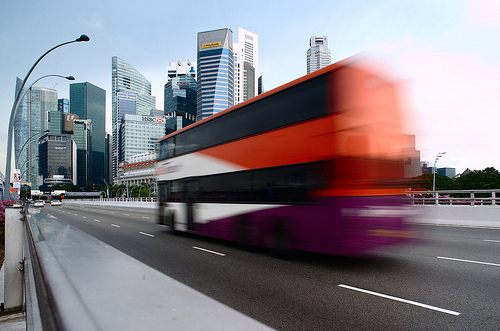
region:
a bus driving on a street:
[141, 125, 443, 272]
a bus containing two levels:
[146, 129, 383, 256]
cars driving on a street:
[33, 193, 69, 208]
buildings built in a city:
[66, 84, 199, 132]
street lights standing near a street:
[0, 39, 78, 204]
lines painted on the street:
[79, 209, 161, 259]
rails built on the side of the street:
[435, 183, 499, 219]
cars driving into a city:
[26, 184, 69, 215]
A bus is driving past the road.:
[143, 52, 431, 259]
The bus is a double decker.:
[148, 53, 412, 257]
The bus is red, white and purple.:
[151, 57, 413, 260]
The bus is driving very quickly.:
[148, 50, 435, 262]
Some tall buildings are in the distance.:
[15, 28, 342, 196]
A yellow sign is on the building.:
[196, 30, 232, 52]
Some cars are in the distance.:
[26, 187, 69, 210]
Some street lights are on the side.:
[1, 27, 98, 208]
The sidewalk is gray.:
[26, 200, 281, 329]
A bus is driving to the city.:
[0, 0, 497, 330]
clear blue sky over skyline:
[1, 0, 493, 175]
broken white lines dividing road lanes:
[30, 200, 490, 326]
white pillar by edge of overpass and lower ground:
[0, 195, 35, 325]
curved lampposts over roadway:
[5, 30, 91, 210]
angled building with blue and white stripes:
[195, 25, 232, 115]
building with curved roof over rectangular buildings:
[110, 52, 160, 192]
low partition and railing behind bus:
[345, 181, 495, 226]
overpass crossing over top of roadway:
[21, 180, 106, 210]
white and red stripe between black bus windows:
[151, 62, 359, 202]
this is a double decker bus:
[135, 65, 413, 292]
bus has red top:
[116, 67, 411, 177]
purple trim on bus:
[145, 181, 450, 291]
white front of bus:
[126, 138, 271, 241]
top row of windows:
[133, 74, 350, 152]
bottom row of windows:
[154, 167, 336, 219]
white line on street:
[336, 267, 460, 327]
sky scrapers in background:
[0, 18, 314, 209]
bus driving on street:
[51, 57, 478, 329]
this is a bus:
[102, 57, 442, 248]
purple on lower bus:
[120, 148, 397, 272]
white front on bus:
[129, 122, 257, 249]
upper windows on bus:
[145, 71, 356, 162]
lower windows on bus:
[135, 160, 360, 232]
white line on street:
[331, 270, 476, 330]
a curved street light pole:
[14, 16, 127, 221]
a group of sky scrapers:
[6, 21, 280, 236]